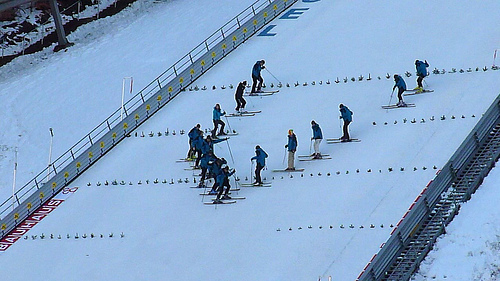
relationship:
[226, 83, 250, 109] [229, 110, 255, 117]
man wearing skis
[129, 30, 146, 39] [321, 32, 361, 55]
snow on path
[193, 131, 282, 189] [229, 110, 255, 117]
people are on skis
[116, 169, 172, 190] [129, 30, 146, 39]
objects are in snow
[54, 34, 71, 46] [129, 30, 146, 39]
tree trunk in snow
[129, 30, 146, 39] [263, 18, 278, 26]
snow on metal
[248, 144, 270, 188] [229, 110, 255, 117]
people wearing skis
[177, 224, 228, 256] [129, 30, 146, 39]
slope covered in snow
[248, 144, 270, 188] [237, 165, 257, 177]
people holding ski pole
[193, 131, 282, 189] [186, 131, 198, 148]
people are wearing jacket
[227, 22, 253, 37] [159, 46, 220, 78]
signs are on boundary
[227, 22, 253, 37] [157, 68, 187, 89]
signs are on fence